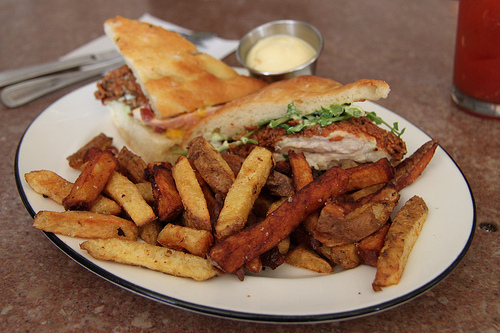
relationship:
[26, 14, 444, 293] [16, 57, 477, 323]
food on plate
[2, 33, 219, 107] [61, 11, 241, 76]
silverware on napkin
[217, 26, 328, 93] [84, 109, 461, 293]
cup on plate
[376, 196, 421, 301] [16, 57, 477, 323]
fry on plate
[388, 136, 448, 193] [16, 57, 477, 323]
fry on plate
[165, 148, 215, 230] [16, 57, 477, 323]
fry on plate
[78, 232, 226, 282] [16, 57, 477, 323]
fry on plate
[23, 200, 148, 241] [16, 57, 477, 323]
fry on plate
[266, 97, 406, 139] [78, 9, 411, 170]
lettuce on sandwich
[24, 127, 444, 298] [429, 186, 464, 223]
fries on plate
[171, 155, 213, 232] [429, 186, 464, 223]
potatoe on plate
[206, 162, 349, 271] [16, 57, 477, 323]
potatoe on plate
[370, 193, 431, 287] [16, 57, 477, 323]
potatoe on plate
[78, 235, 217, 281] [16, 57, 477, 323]
potatoe on plate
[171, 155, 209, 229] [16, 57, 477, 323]
potatoe on plate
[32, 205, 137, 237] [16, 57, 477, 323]
potatoe on plate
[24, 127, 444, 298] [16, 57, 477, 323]
fries on plate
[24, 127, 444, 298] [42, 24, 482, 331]
fries on plate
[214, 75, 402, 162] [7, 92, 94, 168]
sandwhich on plate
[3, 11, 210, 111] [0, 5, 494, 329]
utensils on table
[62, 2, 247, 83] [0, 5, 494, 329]
napkin on table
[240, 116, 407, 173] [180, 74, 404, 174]
chicken in sandwich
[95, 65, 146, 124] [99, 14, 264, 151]
chicken in sandwich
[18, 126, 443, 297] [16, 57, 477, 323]
fries on a plate